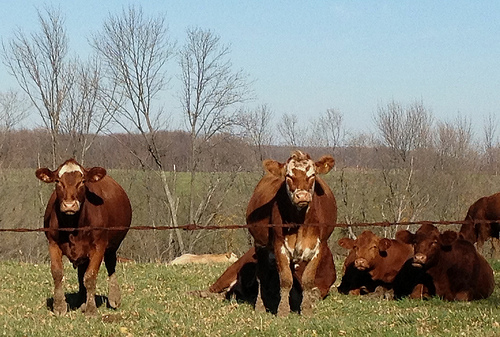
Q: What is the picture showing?
A: It is showing a field.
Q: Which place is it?
A: It is a field.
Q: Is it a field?
A: Yes, it is a field.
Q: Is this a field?
A: Yes, it is a field.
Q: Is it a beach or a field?
A: It is a field.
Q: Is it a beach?
A: No, it is a field.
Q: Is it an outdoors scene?
A: Yes, it is outdoors.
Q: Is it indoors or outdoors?
A: It is outdoors.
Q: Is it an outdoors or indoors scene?
A: It is outdoors.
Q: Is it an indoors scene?
A: No, it is outdoors.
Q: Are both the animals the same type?
A: Yes, all the animals are cows.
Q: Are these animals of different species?
A: No, all the animals are cows.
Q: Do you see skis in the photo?
A: No, there are no skis.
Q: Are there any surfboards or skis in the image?
A: No, there are no skis or surfboards.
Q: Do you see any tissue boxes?
A: No, there are no tissue boxes.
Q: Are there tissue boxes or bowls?
A: No, there are no tissue boxes or bowls.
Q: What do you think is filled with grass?
A: The field is filled with grass.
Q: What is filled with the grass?
A: The field is filled with grass.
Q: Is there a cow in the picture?
A: Yes, there is a cow.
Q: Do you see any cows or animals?
A: Yes, there is a cow.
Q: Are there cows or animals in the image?
A: Yes, there is a cow.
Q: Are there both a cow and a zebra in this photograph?
A: No, there is a cow but no zebras.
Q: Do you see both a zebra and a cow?
A: No, there is a cow but no zebras.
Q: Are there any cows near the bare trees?
A: Yes, there is a cow near the trees.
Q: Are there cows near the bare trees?
A: Yes, there is a cow near the trees.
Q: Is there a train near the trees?
A: No, there is a cow near the trees.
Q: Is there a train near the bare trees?
A: No, there is a cow near the trees.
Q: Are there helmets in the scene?
A: No, there are no helmets.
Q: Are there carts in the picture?
A: No, there are no carts.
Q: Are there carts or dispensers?
A: No, there are no carts or dispensers.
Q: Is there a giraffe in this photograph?
A: No, there are no giraffes.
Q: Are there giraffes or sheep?
A: No, there are no giraffes or sheep.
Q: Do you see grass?
A: Yes, there is grass.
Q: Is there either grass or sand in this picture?
A: Yes, there is grass.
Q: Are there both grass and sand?
A: No, there is grass but no sand.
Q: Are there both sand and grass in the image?
A: No, there is grass but no sand.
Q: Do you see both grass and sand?
A: No, there is grass but no sand.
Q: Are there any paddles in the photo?
A: No, there are no paddles.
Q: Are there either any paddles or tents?
A: No, there are no paddles or tents.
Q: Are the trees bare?
A: Yes, the trees are bare.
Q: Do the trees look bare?
A: Yes, the trees are bare.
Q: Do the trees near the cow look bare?
A: Yes, the trees are bare.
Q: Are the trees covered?
A: No, the trees are bare.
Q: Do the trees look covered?
A: No, the trees are bare.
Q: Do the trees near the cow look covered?
A: No, the trees are bare.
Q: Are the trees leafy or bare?
A: The trees are bare.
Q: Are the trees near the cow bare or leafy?
A: The trees are bare.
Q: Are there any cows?
A: Yes, there is a cow.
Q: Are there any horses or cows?
A: Yes, there is a cow.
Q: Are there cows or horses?
A: Yes, there is a cow.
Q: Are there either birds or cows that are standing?
A: Yes, the cow is standing.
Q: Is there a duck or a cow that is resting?
A: Yes, the cow is resting.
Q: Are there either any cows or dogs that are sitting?
A: Yes, the cow is sitting.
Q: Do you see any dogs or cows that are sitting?
A: Yes, the cow is sitting.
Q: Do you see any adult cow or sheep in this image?
A: Yes, there is an adult cow.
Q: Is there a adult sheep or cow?
A: Yes, there is an adult cow.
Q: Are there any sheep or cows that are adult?
A: Yes, the cow is adult.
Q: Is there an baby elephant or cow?
A: Yes, there is a baby cow.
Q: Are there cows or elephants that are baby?
A: Yes, the cow is a baby.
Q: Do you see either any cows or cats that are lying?
A: Yes, the cow is lying.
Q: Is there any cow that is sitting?
A: Yes, there is a cow that is sitting.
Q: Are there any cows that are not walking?
A: Yes, there is a cow that is sitting.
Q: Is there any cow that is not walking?
A: Yes, there is a cow that is sitting.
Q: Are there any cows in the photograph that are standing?
A: Yes, there is a cow that is standing.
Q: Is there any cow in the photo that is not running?
A: Yes, there is a cow that is standing.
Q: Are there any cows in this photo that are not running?
A: Yes, there is a cow that is standing.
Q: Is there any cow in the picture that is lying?
A: Yes, there is a cow that is lying.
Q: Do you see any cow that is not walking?
A: Yes, there is a cow that is lying .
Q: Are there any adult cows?
A: Yes, there is an adult cow.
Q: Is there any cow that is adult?
A: Yes, there is a cow that is adult.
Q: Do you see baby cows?
A: Yes, there is a baby cow.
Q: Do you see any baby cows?
A: Yes, there is a baby cow.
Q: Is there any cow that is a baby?
A: Yes, there is a cow that is a baby.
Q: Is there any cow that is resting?
A: Yes, there is a cow that is resting.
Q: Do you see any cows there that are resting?
A: Yes, there is a cow that is resting.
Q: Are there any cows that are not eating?
A: Yes, there is a cow that is resting.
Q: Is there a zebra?
A: No, there are no zebras.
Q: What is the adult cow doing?
A: The cow is resting.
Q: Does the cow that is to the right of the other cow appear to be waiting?
A: No, the cow is resting.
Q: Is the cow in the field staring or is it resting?
A: The cow is resting.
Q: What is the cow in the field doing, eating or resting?
A: The cow is resting.